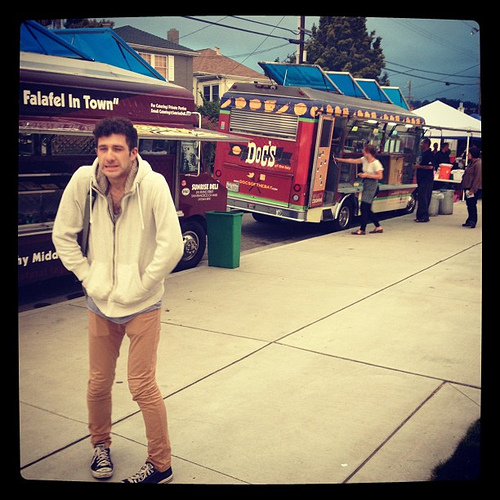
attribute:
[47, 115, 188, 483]
man — standing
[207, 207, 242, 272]
trash can — green, plastic, tall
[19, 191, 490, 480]
sidewalk — grey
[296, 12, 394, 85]
tree — green, large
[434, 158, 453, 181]
cooler — orange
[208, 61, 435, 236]
food truck — red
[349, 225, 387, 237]
flip flops — brown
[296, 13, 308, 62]
telephone pole — brown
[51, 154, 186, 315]
sweatshirt — white, light colored, long sleeved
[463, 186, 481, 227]
pants — black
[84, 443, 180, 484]
sneakers — dark blue, white, black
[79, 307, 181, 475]
pants — tan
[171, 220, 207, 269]
truck tire — rubber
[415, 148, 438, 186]
shirt — black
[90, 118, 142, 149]
hair — dark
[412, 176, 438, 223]
pants — black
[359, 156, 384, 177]
shirt — white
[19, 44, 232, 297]
truck — purple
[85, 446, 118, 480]
tennis shoe — black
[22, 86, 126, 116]
writing — white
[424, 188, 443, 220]
trash can — metal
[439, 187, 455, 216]
trash can — metal